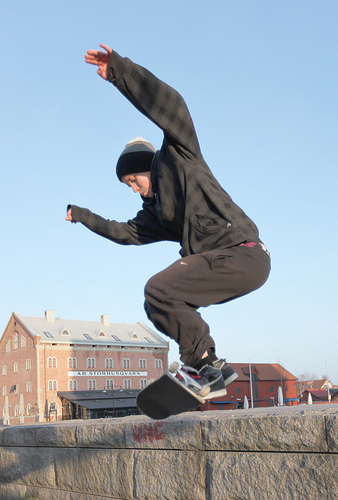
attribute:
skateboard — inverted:
[135, 359, 216, 424]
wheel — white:
[166, 359, 181, 376]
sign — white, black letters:
[74, 360, 148, 383]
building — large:
[1, 307, 172, 422]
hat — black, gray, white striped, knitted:
[111, 135, 159, 180]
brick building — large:
[9, 309, 143, 415]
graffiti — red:
[128, 422, 163, 448]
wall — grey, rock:
[7, 410, 337, 484]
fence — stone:
[0, 402, 336, 498]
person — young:
[64, 43, 271, 400]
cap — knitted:
[116, 136, 156, 181]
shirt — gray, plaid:
[67, 48, 263, 255]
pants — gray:
[143, 245, 272, 367]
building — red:
[185, 328, 321, 449]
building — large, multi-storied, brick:
[0, 304, 187, 441]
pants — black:
[129, 240, 300, 376]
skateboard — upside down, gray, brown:
[101, 320, 263, 477]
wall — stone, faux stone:
[30, 351, 114, 393]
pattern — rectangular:
[1, 409, 326, 499]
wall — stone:
[3, 402, 327, 497]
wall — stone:
[4, 428, 327, 493]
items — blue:
[262, 385, 277, 392]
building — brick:
[0, 308, 168, 435]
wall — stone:
[73, 412, 205, 482]